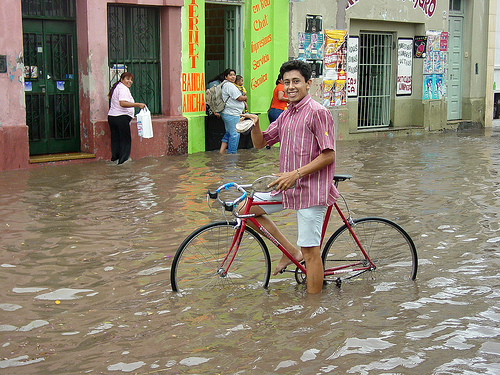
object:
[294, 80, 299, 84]
eye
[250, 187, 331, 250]
short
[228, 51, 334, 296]
man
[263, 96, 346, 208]
shirt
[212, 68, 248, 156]
people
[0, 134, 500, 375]
street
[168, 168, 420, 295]
bicycle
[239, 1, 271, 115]
wall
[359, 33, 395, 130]
front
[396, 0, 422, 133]
wall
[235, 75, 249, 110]
baby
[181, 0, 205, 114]
sign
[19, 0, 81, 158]
door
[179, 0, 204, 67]
writing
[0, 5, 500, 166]
building